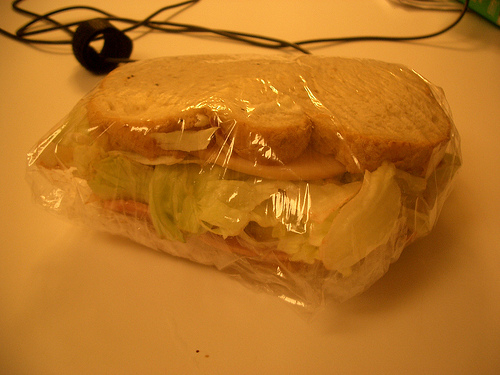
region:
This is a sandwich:
[78, 56, 448, 268]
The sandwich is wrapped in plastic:
[49, 43, 454, 273]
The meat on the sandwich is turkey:
[196, 143, 358, 188]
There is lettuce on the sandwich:
[122, 158, 373, 245]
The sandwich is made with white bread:
[93, 46, 460, 169]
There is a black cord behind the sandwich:
[11, 5, 464, 50]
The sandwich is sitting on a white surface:
[14, 48, 479, 359]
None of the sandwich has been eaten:
[51, 55, 472, 274]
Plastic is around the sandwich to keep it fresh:
[43, 50, 460, 276]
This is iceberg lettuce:
[138, 164, 399, 253]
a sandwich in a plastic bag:
[26, 47, 468, 309]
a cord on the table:
[6, 2, 473, 65]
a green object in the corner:
[463, 1, 498, 31]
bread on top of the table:
[96, 52, 445, 170]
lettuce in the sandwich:
[66, 127, 401, 261]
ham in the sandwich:
[195, 132, 349, 184]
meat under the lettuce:
[101, 190, 300, 265]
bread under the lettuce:
[59, 170, 432, 302]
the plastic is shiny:
[25, 51, 475, 340]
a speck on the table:
[180, 339, 226, 364]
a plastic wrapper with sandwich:
[39, 34, 463, 314]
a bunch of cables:
[4, 1, 476, 65]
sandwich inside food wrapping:
[24, 35, 469, 313]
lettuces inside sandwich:
[79, 150, 413, 269]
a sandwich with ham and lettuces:
[89, 38, 472, 302]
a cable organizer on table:
[68, 17, 138, 78]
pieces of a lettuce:
[306, 164, 414, 275]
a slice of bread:
[92, 44, 464, 175]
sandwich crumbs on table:
[177, 347, 224, 365]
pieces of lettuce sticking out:
[151, 122, 231, 157]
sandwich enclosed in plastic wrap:
[25, 47, 461, 308]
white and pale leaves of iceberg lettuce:
[30, 111, 460, 271]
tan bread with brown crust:
[91, 52, 446, 159]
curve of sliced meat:
[200, 146, 337, 178]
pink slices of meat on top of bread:
[97, 191, 282, 268]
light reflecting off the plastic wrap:
[35, 80, 390, 306]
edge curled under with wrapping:
[65, 190, 250, 270]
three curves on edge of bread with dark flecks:
[95, 110, 435, 165]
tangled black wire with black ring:
[5, 0, 475, 70]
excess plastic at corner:
[25, 155, 85, 220]